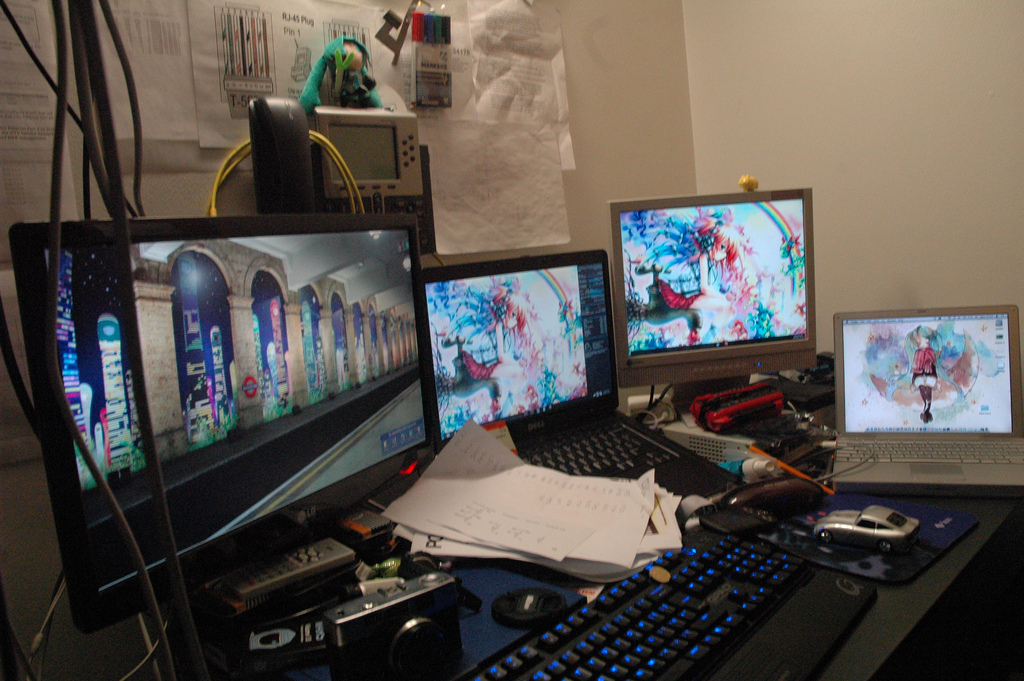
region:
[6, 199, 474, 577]
The large black monitor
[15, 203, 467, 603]
A very large black monitor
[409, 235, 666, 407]
The black laptop monitor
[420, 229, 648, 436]
A screen on the black laptop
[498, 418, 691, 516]
The keyboard on the black laptop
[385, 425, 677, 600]
The stack of papers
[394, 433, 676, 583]
A stack of papers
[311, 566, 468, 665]
The black digital camera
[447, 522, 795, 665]
The lighted keyboard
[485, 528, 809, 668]
A lighted keyboard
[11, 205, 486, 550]
A large black monitor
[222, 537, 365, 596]
The gray remote control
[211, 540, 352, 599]
A gray remote control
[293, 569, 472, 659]
A black digital camera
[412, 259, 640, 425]
The screen on the black laptop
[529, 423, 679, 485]
The keyboard on the black laptop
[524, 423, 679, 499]
A keyboard on the black laptop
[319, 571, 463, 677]
camera sitting on a desk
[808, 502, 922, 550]
silver sports car toy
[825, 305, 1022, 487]
silver laptop sitting on a desk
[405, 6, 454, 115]
markers hanging on a board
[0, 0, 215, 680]
cords hanging down over a computer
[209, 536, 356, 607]
remote control sitting on a computer drive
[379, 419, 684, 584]
stack of papers on a desk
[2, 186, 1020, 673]
several computers on a desk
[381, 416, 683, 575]
A pile of papers on a keyboard.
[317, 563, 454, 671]
A camera on a desk.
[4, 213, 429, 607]
A very large monitor on a desk.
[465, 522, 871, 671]
A blue backlit keyboard.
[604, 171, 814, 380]
A monitor with a small yellow object on top of it.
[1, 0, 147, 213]
Several black cords against a wall.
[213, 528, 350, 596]
A light colored remote on the desk.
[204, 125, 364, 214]
A yellow cord hanging on the wall.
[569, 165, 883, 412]
silver computer monitor on table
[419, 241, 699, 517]
black laptop on table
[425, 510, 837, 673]
black and blue keyboard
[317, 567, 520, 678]
camera on table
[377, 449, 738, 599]
papers on table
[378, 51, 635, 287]
papers on wall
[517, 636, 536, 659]
a key on a keyboard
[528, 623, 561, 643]
a key on a keyboard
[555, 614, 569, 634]
a key on a keyboard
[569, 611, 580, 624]
a key on a keyboard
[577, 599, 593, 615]
a key on a keyboard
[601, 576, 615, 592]
a key on a keyboard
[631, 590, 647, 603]
a key on a keyboard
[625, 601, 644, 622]
a key on a keyboard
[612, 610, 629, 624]
a key on a keyboard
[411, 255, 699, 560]
A black laptop on the desk.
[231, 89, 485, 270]
A telephone on the wall.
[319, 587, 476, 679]
A camera on the desk.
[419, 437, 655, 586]
White papers on the keyboard of the laptop.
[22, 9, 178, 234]
Cords hanging from the back of the monitor.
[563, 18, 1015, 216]
The wall is white.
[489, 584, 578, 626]
The len cover on the desk.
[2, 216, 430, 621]
monitor on the far left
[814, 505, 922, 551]
small silver car on the mouse pad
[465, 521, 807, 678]
black keyboard with blue illuminated keys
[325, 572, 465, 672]
camera behind the keyboard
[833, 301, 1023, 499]
silver laptop on the far right